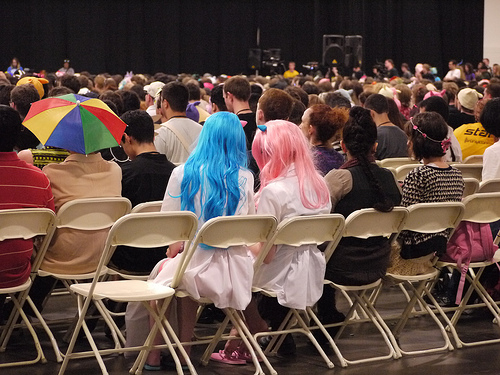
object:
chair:
[57, 209, 199, 373]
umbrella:
[20, 91, 129, 157]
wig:
[165, 110, 254, 248]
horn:
[256, 125, 267, 132]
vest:
[326, 164, 403, 287]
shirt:
[0, 148, 56, 290]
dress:
[127, 162, 257, 313]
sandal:
[209, 349, 247, 366]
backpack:
[444, 221, 496, 305]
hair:
[249, 119, 332, 213]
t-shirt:
[449, 122, 498, 160]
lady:
[7, 57, 24, 75]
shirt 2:
[152, 115, 205, 168]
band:
[408, 115, 452, 153]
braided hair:
[341, 105, 394, 215]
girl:
[222, 115, 332, 365]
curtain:
[1, 0, 484, 74]